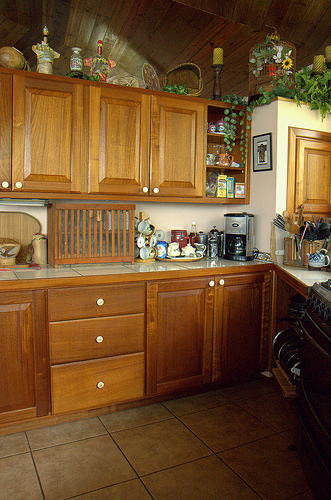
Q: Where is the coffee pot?
A: On the counter.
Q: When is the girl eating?
A: No girl.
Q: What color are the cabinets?
A: Brown.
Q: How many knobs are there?
A: Nine.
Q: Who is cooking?
A: No one.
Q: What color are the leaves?
A: Green.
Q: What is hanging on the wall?
A: Picture.